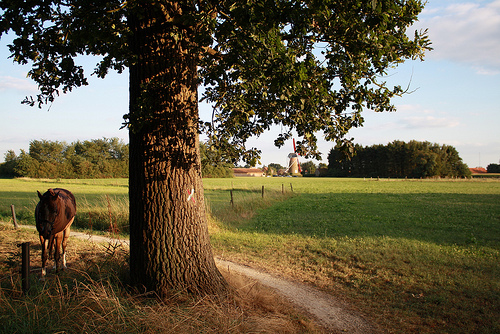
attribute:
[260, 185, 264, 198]
stick — small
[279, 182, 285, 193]
stick — small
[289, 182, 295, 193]
stick — small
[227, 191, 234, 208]
stick — small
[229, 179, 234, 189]
stick — small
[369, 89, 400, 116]
leaves — green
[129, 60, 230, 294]
trunk — long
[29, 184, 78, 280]
horse — head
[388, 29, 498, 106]
sky — clear, thin, blue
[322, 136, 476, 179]
trees — group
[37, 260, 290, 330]
grass — dry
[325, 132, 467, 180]
trees — green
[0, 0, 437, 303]
tree — big, green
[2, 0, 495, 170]
sky — blue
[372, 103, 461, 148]
clouds — white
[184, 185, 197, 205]
white line — small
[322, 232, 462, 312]
hay — small, tan